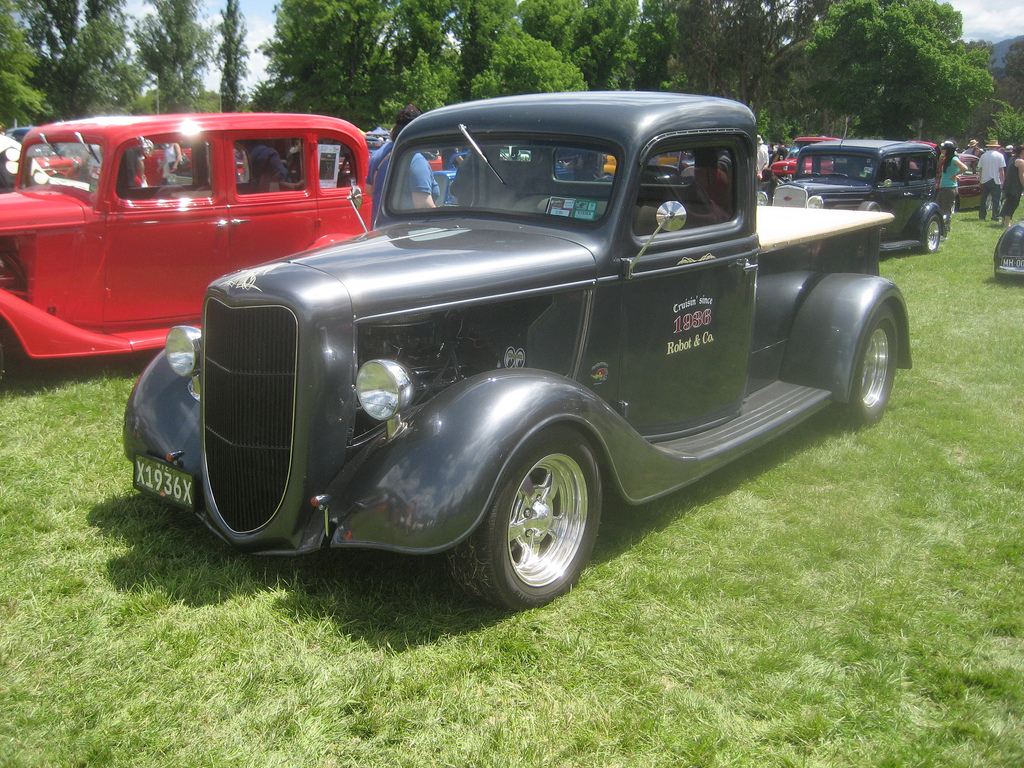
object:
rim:
[507, 453, 587, 588]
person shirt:
[364, 104, 441, 232]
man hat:
[985, 139, 1001, 146]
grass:
[0, 196, 1024, 768]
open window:
[629, 128, 757, 249]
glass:
[383, 132, 626, 231]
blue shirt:
[939, 156, 959, 189]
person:
[936, 143, 969, 241]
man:
[977, 139, 1007, 221]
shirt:
[974, 148, 987, 159]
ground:
[666, 509, 1024, 768]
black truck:
[121, 90, 910, 613]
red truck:
[0, 113, 372, 359]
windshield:
[17, 142, 104, 194]